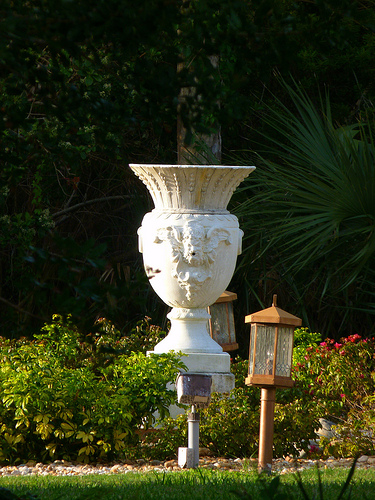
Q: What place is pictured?
A: It is a forest.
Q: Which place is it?
A: It is a forest.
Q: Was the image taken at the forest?
A: Yes, it was taken in the forest.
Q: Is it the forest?
A: Yes, it is the forest.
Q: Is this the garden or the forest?
A: It is the forest.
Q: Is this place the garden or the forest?
A: It is the forest.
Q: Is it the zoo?
A: No, it is the forest.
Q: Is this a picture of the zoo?
A: No, the picture is showing the forest.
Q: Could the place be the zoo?
A: No, it is the forest.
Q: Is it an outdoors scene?
A: Yes, it is outdoors.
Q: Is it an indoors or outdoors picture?
A: It is outdoors.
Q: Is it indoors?
A: No, it is outdoors.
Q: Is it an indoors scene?
A: No, it is outdoors.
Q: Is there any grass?
A: Yes, there is grass.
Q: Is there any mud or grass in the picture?
A: Yes, there is grass.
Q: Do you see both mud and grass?
A: No, there is grass but no mud.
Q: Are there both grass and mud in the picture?
A: No, there is grass but no mud.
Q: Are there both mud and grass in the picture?
A: No, there is grass but no mud.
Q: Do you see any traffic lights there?
A: No, there are no traffic lights.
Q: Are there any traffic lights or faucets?
A: No, there are no traffic lights or faucets.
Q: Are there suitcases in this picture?
A: No, there are no suitcases.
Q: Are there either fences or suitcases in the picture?
A: No, there are no suitcases or fences.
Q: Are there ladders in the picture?
A: No, there are no ladders.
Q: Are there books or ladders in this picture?
A: No, there are no ladders or books.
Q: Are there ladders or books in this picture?
A: No, there are no ladders or books.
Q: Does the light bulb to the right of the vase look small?
A: Yes, the bulb is small.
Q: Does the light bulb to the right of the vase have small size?
A: Yes, the bulb is small.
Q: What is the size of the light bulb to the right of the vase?
A: The bulb is small.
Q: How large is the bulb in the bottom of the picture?
A: The bulb is small.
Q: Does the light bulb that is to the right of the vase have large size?
A: No, the bulb is small.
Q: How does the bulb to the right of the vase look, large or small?
A: The light bulb is small.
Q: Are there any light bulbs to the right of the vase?
A: Yes, there is a light bulb to the right of the vase.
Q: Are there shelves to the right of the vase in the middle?
A: No, there is a light bulb to the right of the vase.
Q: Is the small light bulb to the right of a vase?
A: Yes, the light bulb is to the right of a vase.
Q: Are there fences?
A: No, there are no fences.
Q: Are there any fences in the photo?
A: No, there are no fences.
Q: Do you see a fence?
A: No, there are no fences.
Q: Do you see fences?
A: No, there are no fences.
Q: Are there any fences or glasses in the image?
A: No, there are no fences or glasses.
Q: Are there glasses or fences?
A: No, there are no fences or glasses.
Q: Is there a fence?
A: No, there are no fences.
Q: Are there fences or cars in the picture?
A: No, there are no fences or cars.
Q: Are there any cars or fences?
A: No, there are no fences or cars.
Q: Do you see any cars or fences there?
A: No, there are no fences or cars.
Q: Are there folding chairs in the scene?
A: No, there are no folding chairs.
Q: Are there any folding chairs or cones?
A: No, there are no folding chairs or cones.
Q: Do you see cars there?
A: No, there are no cars.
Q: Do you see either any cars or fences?
A: No, there are no cars or fences.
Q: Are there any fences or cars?
A: No, there are no cars or fences.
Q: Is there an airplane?
A: No, there are no airplanes.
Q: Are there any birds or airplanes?
A: No, there are no airplanes or birds.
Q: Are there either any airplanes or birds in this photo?
A: No, there are no airplanes or birds.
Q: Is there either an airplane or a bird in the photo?
A: No, there are no airplanes or birds.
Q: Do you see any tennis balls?
A: No, there are no tennis balls.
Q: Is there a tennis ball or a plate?
A: No, there are no tennis balls or plates.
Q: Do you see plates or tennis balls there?
A: No, there are no tennis balls or plates.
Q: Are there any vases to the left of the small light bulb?
A: Yes, there is a vase to the left of the bulb.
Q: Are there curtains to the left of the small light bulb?
A: No, there is a vase to the left of the bulb.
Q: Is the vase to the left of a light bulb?
A: Yes, the vase is to the left of a light bulb.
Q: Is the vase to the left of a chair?
A: No, the vase is to the left of a light bulb.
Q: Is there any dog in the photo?
A: No, there are no dogs.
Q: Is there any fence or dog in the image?
A: No, there are no dogs or fences.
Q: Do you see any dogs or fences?
A: No, there are no dogs or fences.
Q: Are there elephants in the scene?
A: No, there are no elephants.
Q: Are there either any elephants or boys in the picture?
A: No, there are no elephants or boys.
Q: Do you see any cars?
A: No, there are no cars.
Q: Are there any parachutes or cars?
A: No, there are no cars or parachutes.